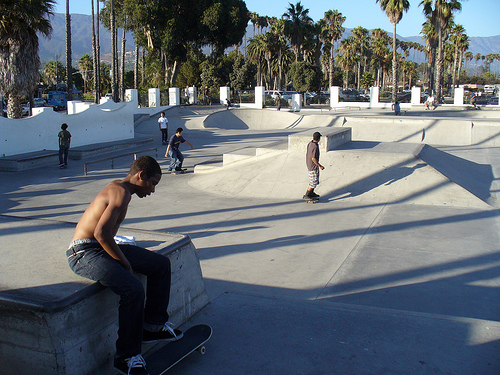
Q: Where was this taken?
A: Skate park.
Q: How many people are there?
A: 5.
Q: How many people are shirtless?
A: 1.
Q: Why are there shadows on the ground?
A: Sunny.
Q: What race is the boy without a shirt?
A: African American.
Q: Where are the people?
A: At a skatepark.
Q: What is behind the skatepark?
A: Trees.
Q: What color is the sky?
A: Blue.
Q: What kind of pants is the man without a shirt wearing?
A: Jeans.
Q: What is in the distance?
A: Mountains.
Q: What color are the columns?
A: White.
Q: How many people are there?
A: 5.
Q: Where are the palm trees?
A: Behind the skate park.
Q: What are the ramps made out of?
A: Cement.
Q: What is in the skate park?
A: Ramps and rails.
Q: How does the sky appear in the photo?
A: Blue and clear.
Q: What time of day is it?
A: Daytime.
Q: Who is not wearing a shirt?
A: The man in the foreground.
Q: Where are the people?
A: At a skatepark.